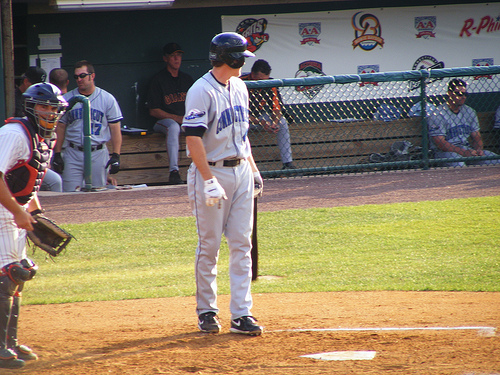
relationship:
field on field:
[17, 194, 499, 309] [0, 164, 498, 371]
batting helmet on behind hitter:
[21, 81, 68, 141] [0, 82, 76, 362]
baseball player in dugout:
[423, 77, 500, 167] [0, 62, 498, 191]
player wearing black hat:
[140, 40, 196, 185] [159, 40, 195, 61]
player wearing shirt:
[140, 40, 196, 185] [140, 66, 192, 131]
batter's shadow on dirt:
[51, 320, 256, 367] [0, 292, 498, 370]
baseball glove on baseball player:
[203, 176, 229, 211] [181, 32, 270, 338]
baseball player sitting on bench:
[423, 77, 500, 167] [110, 110, 499, 187]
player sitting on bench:
[238, 60, 295, 170] [110, 110, 499, 187]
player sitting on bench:
[140, 40, 190, 181] [110, 110, 499, 187]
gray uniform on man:
[60, 86, 138, 192] [49, 59, 124, 192]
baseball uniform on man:
[178, 72, 299, 319] [49, 59, 124, 192]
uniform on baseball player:
[423, 100, 495, 168] [423, 77, 500, 167]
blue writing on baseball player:
[213, 101, 259, 134] [181, 32, 270, 338]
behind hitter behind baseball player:
[0, 82, 76, 362] [181, 32, 270, 338]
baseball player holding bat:
[181, 32, 270, 338] [250, 195, 260, 281]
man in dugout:
[397, 37, 471, 160] [285, 39, 490, 177]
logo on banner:
[345, 0, 395, 63] [283, 19, 484, 75]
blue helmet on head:
[21, 80, 75, 116] [12, 68, 57, 133]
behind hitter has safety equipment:
[0, 82, 76, 362] [24, 84, 73, 135]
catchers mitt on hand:
[20, 209, 78, 257] [21, 205, 73, 281]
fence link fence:
[246, 72, 499, 175] [326, 95, 398, 164]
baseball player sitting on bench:
[423, 77, 500, 167] [319, 86, 480, 164]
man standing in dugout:
[57, 48, 133, 188] [23, 30, 206, 184]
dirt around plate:
[248, 341, 260, 371] [303, 332, 373, 370]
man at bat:
[49, 59, 124, 192] [250, 179, 264, 300]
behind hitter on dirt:
[0, 82, 76, 362] [59, 286, 166, 371]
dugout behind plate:
[61, 23, 197, 203] [276, 317, 376, 371]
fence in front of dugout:
[246, 72, 499, 175] [279, 70, 415, 173]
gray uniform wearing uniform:
[427, 93, 494, 169] [176, 75, 279, 327]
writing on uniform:
[214, 97, 244, 137] [168, 85, 304, 335]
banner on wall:
[272, 10, 390, 75] [259, 14, 477, 108]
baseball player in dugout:
[423, 77, 500, 167] [310, 17, 477, 180]